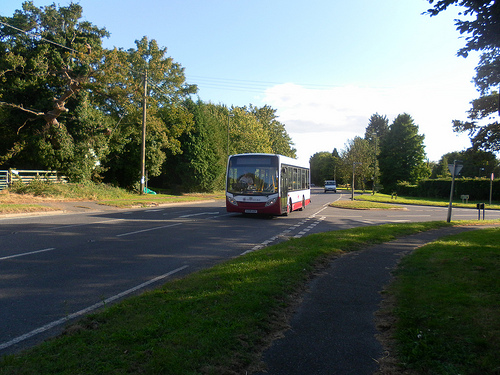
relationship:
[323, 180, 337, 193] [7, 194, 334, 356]
van on road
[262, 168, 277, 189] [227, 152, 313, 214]
driver driving bus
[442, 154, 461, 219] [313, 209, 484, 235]
pole on corner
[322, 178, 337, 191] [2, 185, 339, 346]
van driving on road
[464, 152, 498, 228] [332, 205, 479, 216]
mailbox near to road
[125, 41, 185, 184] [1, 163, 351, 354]
tree near to road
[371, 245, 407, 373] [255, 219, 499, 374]
mowed grass next to sidewalk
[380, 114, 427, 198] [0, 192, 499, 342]
tree next to road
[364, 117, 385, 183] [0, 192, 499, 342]
tree next to road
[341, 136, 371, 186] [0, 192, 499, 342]
tree next to road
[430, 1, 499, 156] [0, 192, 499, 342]
tree next to road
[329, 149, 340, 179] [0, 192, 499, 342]
tree next to road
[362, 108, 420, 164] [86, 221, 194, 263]
tree next to road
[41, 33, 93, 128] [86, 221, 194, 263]
tree next to road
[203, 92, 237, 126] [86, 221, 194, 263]
tree next to road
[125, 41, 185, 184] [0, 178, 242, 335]
tree next to road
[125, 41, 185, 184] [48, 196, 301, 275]
tree next to road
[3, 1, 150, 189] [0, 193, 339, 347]
tree next to driveway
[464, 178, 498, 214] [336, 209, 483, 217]
sign next to road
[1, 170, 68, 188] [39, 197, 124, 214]
fence in front driveway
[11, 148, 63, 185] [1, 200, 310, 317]
fence next to road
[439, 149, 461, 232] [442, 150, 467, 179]
sign has back